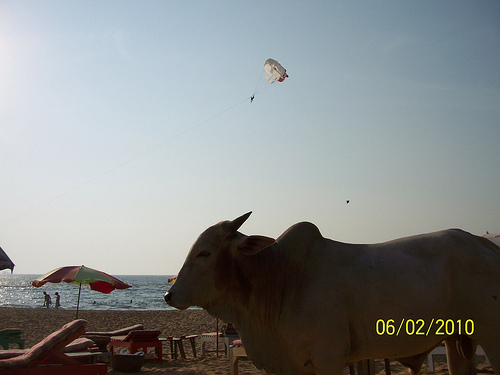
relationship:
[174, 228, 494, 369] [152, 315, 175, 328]
bull on beach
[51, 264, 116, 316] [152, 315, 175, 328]
umbrella on beach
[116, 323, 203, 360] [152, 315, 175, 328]
benches are on beach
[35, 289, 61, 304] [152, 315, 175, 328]
couple walking along beach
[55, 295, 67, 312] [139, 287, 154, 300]
people are in water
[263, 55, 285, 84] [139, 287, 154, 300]
parasail over water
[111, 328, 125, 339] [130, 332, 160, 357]
cushions are on lounger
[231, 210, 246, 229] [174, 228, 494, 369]
horn on bull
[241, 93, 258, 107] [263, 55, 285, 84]
person on parasail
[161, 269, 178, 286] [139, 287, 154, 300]
objects are in water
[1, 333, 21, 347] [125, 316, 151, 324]
basket on sand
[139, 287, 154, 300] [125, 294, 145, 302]
water in ocean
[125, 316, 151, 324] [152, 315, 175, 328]
sand on beach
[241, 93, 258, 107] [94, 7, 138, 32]
person in sky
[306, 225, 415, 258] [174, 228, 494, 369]
hump on bull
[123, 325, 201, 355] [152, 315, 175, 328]
furniture on beach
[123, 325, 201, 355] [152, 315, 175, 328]
furniture for beach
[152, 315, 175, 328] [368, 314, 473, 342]
beach on 06/02/2010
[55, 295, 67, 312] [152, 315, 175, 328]
people are on beach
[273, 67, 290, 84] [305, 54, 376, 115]
kite in air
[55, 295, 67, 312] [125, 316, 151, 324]
people are walking in sand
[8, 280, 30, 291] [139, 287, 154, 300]
sun shining on water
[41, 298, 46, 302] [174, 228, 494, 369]
hand reaching to bull